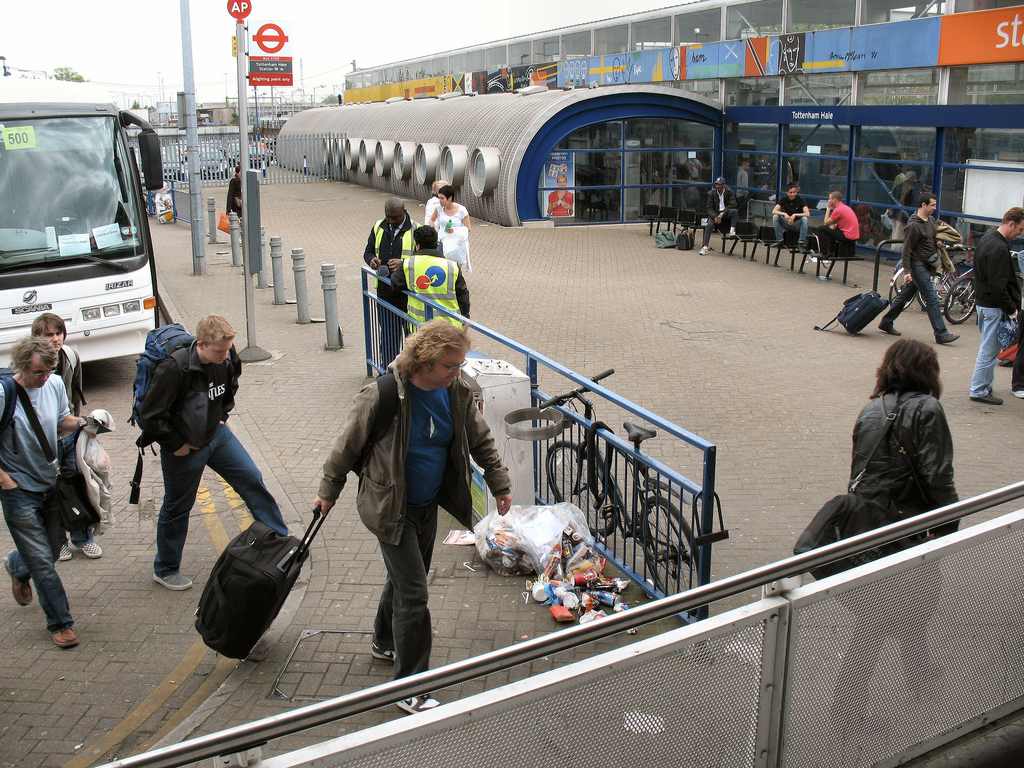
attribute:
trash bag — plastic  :
[454, 482, 599, 586]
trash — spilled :
[527, 521, 625, 638]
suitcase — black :
[182, 514, 332, 677]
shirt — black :
[140, 343, 244, 467]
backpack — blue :
[115, 318, 204, 465]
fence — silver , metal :
[348, 237, 727, 676]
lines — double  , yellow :
[71, 384, 273, 706]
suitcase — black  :
[130, 458, 377, 677]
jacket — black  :
[125, 309, 257, 487]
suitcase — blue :
[130, 318, 208, 461]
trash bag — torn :
[436, 490, 631, 594]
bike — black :
[514, 361, 711, 653]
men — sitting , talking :
[771, 149, 906, 310]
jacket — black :
[698, 177, 740, 238]